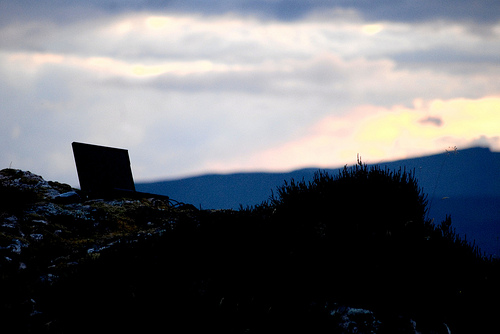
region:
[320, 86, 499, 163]
A purple sunset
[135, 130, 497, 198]
The horizon in the distance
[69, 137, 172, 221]
A black box on a hillside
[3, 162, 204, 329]
A rocky hillside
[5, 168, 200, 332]
A rocky terrain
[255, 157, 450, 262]
A small bush on the hill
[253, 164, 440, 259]
Small group of vegetation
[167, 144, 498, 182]
A mountain range in the distance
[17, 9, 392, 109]
Fluffy clouds in the sky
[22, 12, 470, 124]
The sky is cloudy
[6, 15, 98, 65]
white clouds in blue sky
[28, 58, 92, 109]
white clouds in blue sky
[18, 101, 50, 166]
white clouds in blue sky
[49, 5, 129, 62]
white clouds in blue sky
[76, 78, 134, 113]
white clouds in blue sky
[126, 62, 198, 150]
white clouds in blue sky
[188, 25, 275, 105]
white clouds in blue sky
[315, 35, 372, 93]
white clouds in blue sky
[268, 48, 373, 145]
white clouds in blue sky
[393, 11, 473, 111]
white clouds in blue sky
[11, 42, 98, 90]
white clouds in blue sky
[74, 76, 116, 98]
white clouds in blue sky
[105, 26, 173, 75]
white clouds in blue sky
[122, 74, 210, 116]
white clouds in blue sky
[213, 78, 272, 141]
white clouds in blue sky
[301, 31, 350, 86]
white clouds in blue sky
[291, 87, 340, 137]
white clouds in blue sky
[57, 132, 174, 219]
laptop facing the mountain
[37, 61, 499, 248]
laptop facing the mountain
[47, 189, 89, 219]
rocks on the ground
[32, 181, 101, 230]
rocks on the ground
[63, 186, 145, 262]
rocks on the ground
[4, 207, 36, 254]
rocks on the ground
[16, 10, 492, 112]
line of clouds in sky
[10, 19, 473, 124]
clouds above the mountains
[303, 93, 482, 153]
sunlight coming through clouds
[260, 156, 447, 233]
grass growing on mountain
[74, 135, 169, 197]
open laptop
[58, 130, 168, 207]
laptop sitting on mountaintop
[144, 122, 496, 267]
mountain on the horizon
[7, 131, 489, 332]
mountaintop laptop is sitting on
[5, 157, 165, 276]
rocky surface laptop is on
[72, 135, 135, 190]
lid of the laptop